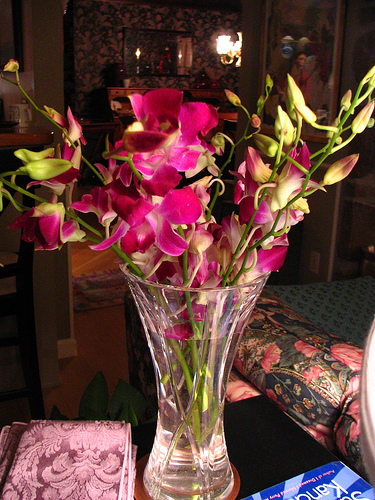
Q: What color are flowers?
A: Pink.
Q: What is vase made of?
A: Glass.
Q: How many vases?
A: One.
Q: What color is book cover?
A: Blue.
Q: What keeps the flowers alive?
A: Water.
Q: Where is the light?
A: Behind the vase.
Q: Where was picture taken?
A: In a living room.